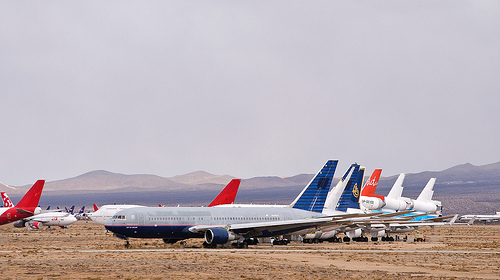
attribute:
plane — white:
[28, 201, 78, 226]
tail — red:
[208, 169, 248, 207]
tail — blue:
[291, 157, 338, 210]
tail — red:
[16, 178, 46, 216]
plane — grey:
[100, 157, 354, 251]